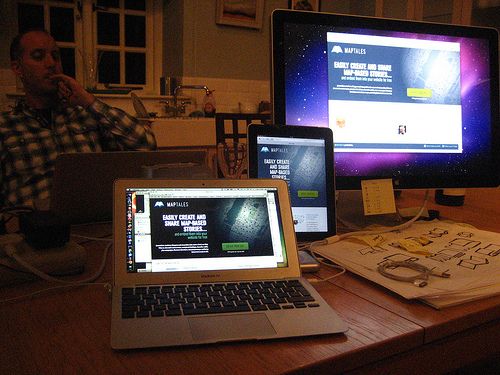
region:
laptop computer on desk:
[110, 173, 335, 358]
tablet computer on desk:
[245, 117, 340, 247]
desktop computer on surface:
[271, 6, 488, 196]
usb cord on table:
[380, 245, 454, 293]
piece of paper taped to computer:
[354, 172, 400, 219]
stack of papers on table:
[376, 230, 488, 302]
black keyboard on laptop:
[171, 281, 303, 306]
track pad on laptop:
[192, 310, 277, 338]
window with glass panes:
[83, 4, 158, 89]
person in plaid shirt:
[21, 35, 168, 194]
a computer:
[72, 126, 313, 361]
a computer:
[130, 190, 191, 252]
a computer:
[135, 208, 317, 371]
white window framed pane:
[40, 6, 222, 117]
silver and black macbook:
[115, 174, 344, 346]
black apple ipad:
[250, 107, 356, 253]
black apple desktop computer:
[268, 11, 484, 194]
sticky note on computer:
[346, 167, 411, 220]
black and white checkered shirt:
[7, 113, 116, 185]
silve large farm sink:
[167, 75, 213, 145]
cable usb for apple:
[384, 249, 439, 299]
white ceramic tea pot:
[234, 93, 259, 122]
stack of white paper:
[338, 216, 478, 312]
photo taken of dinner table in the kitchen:
[6, 3, 494, 368]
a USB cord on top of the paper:
[374, 248, 457, 300]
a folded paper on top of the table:
[312, 215, 494, 305]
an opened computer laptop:
[102, 173, 351, 350]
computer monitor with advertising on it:
[266, 6, 495, 181]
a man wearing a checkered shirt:
[6, 19, 145, 220]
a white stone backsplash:
[116, 73, 269, 119]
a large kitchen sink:
[131, 76, 243, 149]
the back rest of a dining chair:
[211, 106, 272, 179]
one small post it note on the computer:
[355, 174, 403, 219]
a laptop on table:
[51, 151, 396, 368]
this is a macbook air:
[79, 136, 393, 367]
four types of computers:
[53, 13, 485, 360]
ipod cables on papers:
[354, 234, 495, 339]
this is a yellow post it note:
[342, 162, 424, 224]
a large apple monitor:
[254, 8, 499, 245]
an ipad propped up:
[225, 110, 387, 250]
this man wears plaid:
[6, 22, 163, 219]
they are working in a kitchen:
[17, 9, 478, 271]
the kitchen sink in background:
[128, 37, 304, 153]